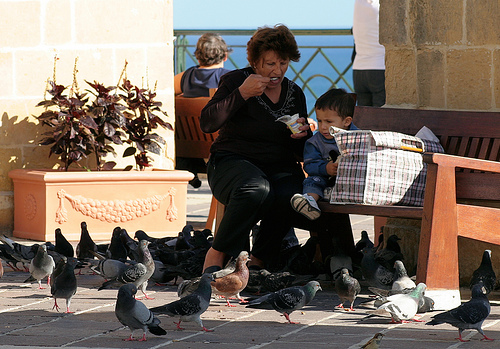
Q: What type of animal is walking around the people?
A: Birds.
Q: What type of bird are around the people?
A: Pigeons.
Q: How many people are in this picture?
A: 3.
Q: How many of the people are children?
A: 1.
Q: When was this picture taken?
A: Daytime.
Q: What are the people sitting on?
A: Benches.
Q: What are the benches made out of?
A: Wood.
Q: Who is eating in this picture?
A: The adult woman.